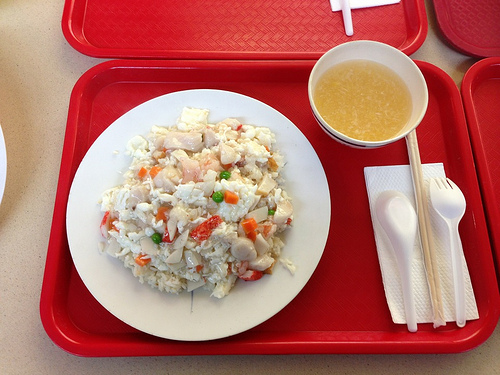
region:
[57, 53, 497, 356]
red plastic cafeteria tray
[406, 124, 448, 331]
two wooden chop sticks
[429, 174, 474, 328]
white plastic disposable spork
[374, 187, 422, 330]
white plastic disposable spoon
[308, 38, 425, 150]
chicken noodle soup bowl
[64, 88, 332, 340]
white plastic dinner plate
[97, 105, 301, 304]
chickem with rice carrots and peas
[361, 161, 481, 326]
white paper dinner napkin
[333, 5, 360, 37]
white plastic spoon handle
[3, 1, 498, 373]
white plastic cafeteria table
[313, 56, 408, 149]
egg drop soup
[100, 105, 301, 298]
chicken with rice and vegetables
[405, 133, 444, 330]
two chop sticks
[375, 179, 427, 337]
white soup spoon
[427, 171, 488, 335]
white plastic spork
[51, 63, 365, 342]
large white round plate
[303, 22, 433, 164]
small white soup bowl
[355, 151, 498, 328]
white paper napkin on tray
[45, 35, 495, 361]
red plastic food carrying tray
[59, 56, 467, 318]
full chinese meal on tray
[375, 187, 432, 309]
shiny white plastic spoon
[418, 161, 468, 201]
tines in plastic fork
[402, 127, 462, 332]
long brown wooden chop sticks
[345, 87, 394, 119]
egg particles in broth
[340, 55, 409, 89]
white inside of bowl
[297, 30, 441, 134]
bowl of egg drop soup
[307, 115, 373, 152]
small blue line on white bowl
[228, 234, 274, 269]
small chunk of chicken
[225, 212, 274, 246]
small pieces of red carrots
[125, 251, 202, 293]
white rice on plate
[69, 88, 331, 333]
plate heaping with rice and vegetables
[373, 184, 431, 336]
plastic asian style spoon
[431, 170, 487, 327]
plastic cafeteria style spork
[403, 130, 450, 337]
pair of wooden chop sticks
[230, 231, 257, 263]
small round scallop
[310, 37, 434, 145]
bowl of asian soup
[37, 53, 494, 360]
lunch on a red tray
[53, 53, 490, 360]
cafeteria style lunch on a tray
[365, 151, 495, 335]
white napkin with utensils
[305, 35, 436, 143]
egg foo yung soup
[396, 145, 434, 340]
a set of wooden chopsticks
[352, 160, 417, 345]
a white soup spoon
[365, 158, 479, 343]
silverware laying on white napkin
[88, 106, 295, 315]
a serving of fried rice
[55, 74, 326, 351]
friend rice on a white plate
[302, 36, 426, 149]
a white bowl of soup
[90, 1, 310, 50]
a red serving tray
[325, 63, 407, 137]
a serving of egg drop soup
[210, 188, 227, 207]
a green pea in rice dish